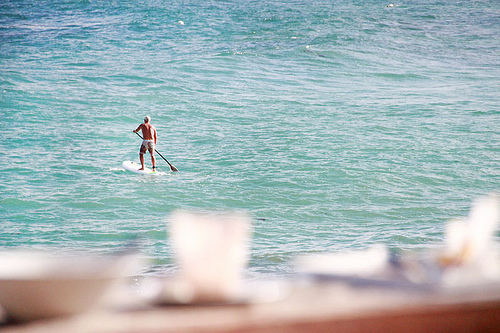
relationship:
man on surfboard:
[133, 116, 159, 172] [110, 155, 180, 196]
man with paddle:
[133, 116, 159, 172] [141, 139, 204, 183]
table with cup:
[175, 284, 460, 321] [148, 197, 281, 273]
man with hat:
[133, 116, 159, 172] [135, 96, 166, 125]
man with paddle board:
[133, 116, 159, 172] [122, 160, 167, 176]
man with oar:
[118, 101, 169, 160] [156, 150, 191, 171]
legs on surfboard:
[125, 147, 167, 172] [111, 152, 174, 191]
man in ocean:
[133, 116, 159, 172] [2, 2, 498, 276]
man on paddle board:
[133, 116, 159, 172] [122, 159, 166, 177]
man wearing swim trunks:
[133, 116, 159, 172] [139, 139, 153, 156]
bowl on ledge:
[1, 247, 147, 317] [2, 275, 499, 331]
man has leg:
[133, 116, 159, 172] [139, 140, 149, 170]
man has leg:
[133, 116, 159, 172] [147, 141, 156, 171]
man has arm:
[133, 116, 159, 172] [132, 122, 142, 132]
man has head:
[133, 116, 159, 172] [142, 113, 149, 123]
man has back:
[133, 116, 159, 172] [141, 121, 154, 140]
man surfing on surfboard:
[133, 116, 159, 172] [122, 158, 171, 177]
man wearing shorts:
[133, 116, 159, 172] [140, 139, 155, 155]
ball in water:
[387, 2, 395, 8] [1, 1, 499, 286]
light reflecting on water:
[2, 1, 499, 286] [1, 1, 499, 286]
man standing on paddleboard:
[133, 116, 159, 172] [123, 158, 169, 176]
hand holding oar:
[132, 125, 140, 135] [132, 129, 179, 172]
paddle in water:
[164, 156, 181, 176] [239, 114, 356, 181]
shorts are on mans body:
[140, 139, 155, 155] [135, 118, 162, 170]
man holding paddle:
[133, 116, 159, 172] [140, 136, 176, 176]